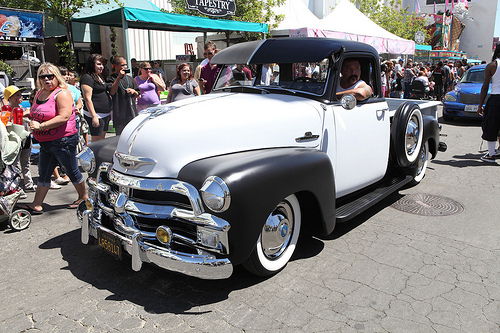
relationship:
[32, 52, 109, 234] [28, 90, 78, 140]
woman wears top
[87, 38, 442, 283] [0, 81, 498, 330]
pickup on street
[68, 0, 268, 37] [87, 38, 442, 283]
awning near pickup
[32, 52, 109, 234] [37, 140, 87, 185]
woman wears jeans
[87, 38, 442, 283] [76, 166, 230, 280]
pickup has bumper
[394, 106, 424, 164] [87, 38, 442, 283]
tire on pickup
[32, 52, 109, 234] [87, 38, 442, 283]
woman next to pickup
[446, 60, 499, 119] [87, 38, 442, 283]
car behind pickup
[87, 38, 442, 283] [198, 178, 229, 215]
pickup has headlight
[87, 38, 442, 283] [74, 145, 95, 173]
pickup has headlight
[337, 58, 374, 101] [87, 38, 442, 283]
man in pickup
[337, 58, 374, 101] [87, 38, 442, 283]
man drives pickup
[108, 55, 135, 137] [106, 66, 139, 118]
man wearing shirt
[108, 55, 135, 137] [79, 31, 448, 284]
man taking picture truck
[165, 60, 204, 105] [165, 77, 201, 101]
lady wears shirt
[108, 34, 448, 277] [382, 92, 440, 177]
truck has tire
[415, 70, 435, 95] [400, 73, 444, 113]
person riding scooter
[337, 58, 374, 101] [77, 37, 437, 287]
man in car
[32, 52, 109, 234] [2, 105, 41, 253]
woman pushing stroller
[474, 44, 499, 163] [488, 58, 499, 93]
man wearing tank top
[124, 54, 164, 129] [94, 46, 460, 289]
woman in truck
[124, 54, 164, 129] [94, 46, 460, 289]
woman looking at truck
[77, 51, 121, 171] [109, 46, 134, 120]
woman standing next to man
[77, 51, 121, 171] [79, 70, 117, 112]
woman in shirt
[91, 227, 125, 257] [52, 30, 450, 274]
plate on truck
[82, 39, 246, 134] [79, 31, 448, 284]
group looking at truck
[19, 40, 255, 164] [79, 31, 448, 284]
people looking at truck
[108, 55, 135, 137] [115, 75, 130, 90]
man wearing necklace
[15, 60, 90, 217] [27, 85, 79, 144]
lady in pink shirt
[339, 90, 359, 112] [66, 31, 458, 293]
mirror on car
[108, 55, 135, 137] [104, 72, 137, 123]
man in shirt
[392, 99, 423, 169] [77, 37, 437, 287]
spare tire on car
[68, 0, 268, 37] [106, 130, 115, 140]
awning over sidewalk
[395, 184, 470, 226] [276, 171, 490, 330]
manhole cover in street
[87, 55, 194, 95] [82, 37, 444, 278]
people looking at restored truck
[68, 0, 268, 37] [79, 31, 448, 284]
awning behind truck